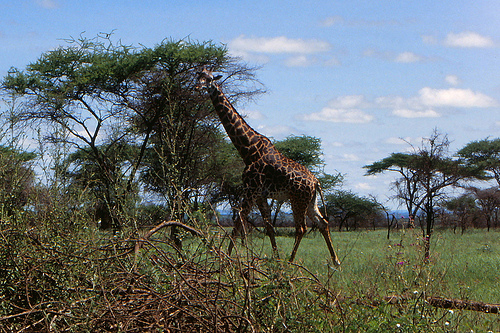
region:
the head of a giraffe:
[190, 62, 225, 94]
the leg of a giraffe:
[283, 195, 311, 265]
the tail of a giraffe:
[314, 179, 331, 224]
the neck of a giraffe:
[211, 83, 272, 160]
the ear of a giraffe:
[213, 69, 227, 82]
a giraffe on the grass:
[188, 64, 348, 270]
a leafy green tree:
[357, 138, 495, 185]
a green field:
[76, 224, 498, 331]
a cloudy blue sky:
[0, 0, 499, 217]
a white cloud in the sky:
[414, 27, 499, 53]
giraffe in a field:
[177, 47, 359, 276]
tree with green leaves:
[346, 135, 486, 285]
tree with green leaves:
[252, 120, 347, 242]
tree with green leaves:
[450, 117, 499, 201]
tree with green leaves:
[2, 24, 261, 256]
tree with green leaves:
[54, 133, 152, 250]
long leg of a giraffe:
[277, 193, 314, 281]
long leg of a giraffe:
[306, 195, 338, 275]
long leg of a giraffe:
[257, 181, 282, 266]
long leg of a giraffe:
[208, 175, 259, 275]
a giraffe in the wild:
[170, 46, 367, 273]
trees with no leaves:
[59, 243, 222, 320]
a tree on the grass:
[334, 123, 467, 277]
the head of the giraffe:
[186, 63, 226, 102]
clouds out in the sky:
[306, 26, 442, 123]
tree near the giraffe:
[35, 18, 162, 123]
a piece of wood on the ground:
[419, 265, 460, 324]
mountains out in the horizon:
[388, 200, 404, 212]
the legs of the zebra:
[229, 211, 373, 274]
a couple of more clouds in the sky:
[302, 54, 489, 127]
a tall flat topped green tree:
[363, 146, 472, 284]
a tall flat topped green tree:
[211, 132, 325, 246]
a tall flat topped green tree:
[456, 133, 498, 233]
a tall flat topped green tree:
[8, 42, 127, 232]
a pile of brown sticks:
[8, 181, 302, 332]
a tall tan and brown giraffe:
[193, 62, 340, 267]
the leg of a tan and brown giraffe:
[305, 196, 350, 272]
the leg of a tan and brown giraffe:
[284, 193, 307, 266]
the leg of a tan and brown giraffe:
[225, 191, 257, 274]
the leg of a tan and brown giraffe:
[252, 189, 283, 254]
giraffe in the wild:
[172, 46, 339, 263]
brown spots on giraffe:
[254, 157, 280, 184]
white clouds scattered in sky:
[318, 63, 465, 125]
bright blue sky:
[135, 11, 201, 40]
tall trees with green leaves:
[59, 27, 209, 245]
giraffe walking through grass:
[129, 57, 399, 287]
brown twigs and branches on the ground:
[99, 219, 279, 324]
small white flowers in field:
[383, 281, 465, 329]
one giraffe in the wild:
[150, 41, 357, 273]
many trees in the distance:
[349, 136, 495, 233]